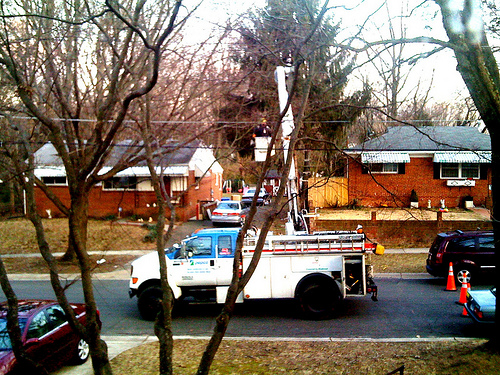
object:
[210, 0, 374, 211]
tree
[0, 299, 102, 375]
car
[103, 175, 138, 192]
window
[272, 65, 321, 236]
crane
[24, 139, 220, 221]
house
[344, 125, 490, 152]
roof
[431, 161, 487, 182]
window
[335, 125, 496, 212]
building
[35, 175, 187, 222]
walls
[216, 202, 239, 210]
rear window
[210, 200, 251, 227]
vehicle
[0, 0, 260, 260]
tree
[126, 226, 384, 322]
truck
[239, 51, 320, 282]
branch part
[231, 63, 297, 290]
branch part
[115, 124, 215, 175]
branch part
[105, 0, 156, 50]
branch part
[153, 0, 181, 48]
branch part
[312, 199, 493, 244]
fence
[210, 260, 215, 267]
door handle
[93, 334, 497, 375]
curb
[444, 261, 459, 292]
cone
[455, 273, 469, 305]
cone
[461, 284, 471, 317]
cone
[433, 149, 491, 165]
awning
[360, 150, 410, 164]
awning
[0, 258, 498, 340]
road